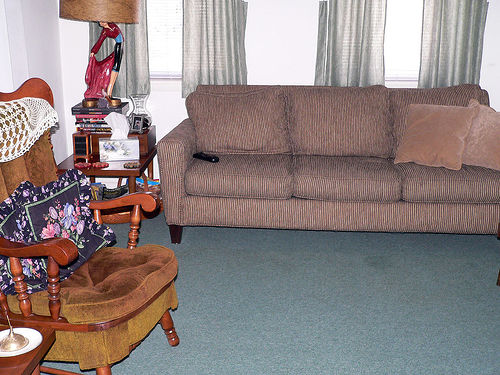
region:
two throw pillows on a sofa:
[390, 98, 497, 173]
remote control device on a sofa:
[192, 148, 222, 166]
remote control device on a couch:
[192, 146, 220, 168]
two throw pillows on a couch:
[392, 100, 498, 169]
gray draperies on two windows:
[88, 0, 489, 100]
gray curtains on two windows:
[89, 3, 487, 99]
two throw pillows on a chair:
[0, 170, 117, 297]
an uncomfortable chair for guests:
[0, 78, 178, 374]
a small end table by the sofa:
[57, 125, 157, 187]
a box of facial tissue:
[97, 112, 141, 161]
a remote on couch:
[188, 148, 219, 164]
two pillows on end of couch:
[393, 88, 498, 182]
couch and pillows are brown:
[138, 68, 498, 257]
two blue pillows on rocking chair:
[1, 174, 118, 301]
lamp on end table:
[54, 2, 146, 97]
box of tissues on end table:
[95, 108, 144, 173]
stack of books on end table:
[68, 95, 126, 140]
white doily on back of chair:
[0, 95, 57, 167]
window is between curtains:
[380, 0, 429, 88]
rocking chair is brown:
[0, 73, 200, 374]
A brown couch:
[157, 82, 498, 255]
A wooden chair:
[2, 76, 183, 373]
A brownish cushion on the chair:
[3, 100, 178, 325]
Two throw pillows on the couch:
[391, 100, 497, 175]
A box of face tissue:
[98, 107, 142, 164]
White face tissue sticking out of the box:
[100, 111, 130, 141]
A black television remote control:
[192, 149, 219, 162]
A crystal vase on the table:
[121, 92, 153, 135]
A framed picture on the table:
[129, 115, 144, 133]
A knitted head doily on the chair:
[0, 96, 58, 166]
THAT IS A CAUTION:
[199, 81, 274, 156]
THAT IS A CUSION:
[291, 96, 386, 154]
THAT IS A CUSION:
[401, 98, 470, 158]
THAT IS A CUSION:
[455, 100, 493, 184]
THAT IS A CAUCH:
[172, 92, 497, 227]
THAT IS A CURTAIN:
[181, 0, 239, 79]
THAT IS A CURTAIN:
[316, 0, 378, 80]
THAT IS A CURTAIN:
[414, 0, 476, 80]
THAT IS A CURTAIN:
[129, 34, 144, 77]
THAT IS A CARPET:
[209, 263, 241, 318]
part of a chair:
[378, 196, 385, 209]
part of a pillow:
[436, 143, 441, 148]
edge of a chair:
[141, 274, 146, 280]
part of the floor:
[318, 315, 321, 329]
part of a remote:
[220, 149, 223, 153]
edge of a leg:
[293, 230, 300, 244]